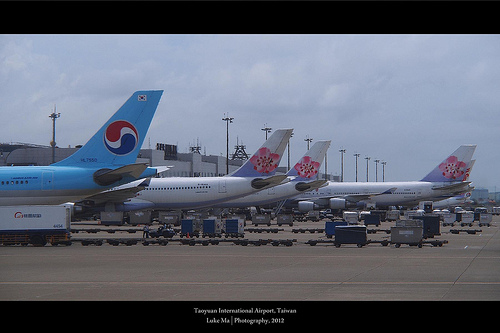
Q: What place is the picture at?
A: It is at the airport.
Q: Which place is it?
A: It is an airport.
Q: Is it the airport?
A: Yes, it is the airport.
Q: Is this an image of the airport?
A: Yes, it is showing the airport.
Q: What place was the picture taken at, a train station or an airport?
A: It was taken at an airport.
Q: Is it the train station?
A: No, it is the airport.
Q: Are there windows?
A: Yes, there are windows.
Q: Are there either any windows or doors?
A: Yes, there are windows.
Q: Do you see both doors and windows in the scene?
A: Yes, there are both windows and doors.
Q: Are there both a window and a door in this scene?
A: Yes, there are both a window and a door.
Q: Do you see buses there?
A: No, there are no buses.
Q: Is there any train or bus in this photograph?
A: No, there are no buses or trains.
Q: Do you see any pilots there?
A: No, there are no pilots.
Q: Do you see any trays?
A: No, there are no trays.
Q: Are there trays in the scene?
A: No, there are no trays.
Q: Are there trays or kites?
A: No, there are no trays or kites.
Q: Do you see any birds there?
A: No, there are no birds.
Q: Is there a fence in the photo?
A: No, there are no fences.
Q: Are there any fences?
A: No, there are no fences.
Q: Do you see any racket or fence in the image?
A: No, there are no fences or rackets.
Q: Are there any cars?
A: No, there are no cars.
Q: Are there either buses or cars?
A: No, there are no cars or buses.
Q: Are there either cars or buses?
A: No, there are no cars or buses.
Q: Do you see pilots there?
A: No, there are no pilots.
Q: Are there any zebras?
A: No, there are no zebras.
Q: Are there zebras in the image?
A: No, there are no zebras.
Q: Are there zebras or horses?
A: No, there are no zebras or horses.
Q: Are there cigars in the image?
A: No, there are no cigars.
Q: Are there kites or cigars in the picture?
A: No, there are no cigars or kites.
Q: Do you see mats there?
A: No, there are no mats.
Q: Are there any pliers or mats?
A: No, there are no mats or pliers.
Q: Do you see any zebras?
A: No, there are no zebras.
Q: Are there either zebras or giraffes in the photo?
A: No, there are no zebras or giraffes.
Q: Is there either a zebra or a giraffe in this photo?
A: No, there are no zebras or giraffes.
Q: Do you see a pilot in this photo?
A: No, there are no pilots.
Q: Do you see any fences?
A: No, there are no fences.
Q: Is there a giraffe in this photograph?
A: No, there are no giraffes.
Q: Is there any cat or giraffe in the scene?
A: No, there are no giraffes or cats.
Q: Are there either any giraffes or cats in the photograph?
A: No, there are no giraffes or cats.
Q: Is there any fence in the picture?
A: No, there are no fences.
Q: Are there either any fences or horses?
A: No, there are no fences or horses.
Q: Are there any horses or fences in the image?
A: No, there are no fences or horses.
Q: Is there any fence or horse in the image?
A: No, there are no fences or horses.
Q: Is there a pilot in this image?
A: No, there are no pilots.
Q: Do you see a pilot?
A: No, there are no pilots.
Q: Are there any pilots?
A: No, there are no pilots.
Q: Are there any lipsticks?
A: No, there are no lipsticks.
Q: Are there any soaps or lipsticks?
A: No, there are no lipsticks or soaps.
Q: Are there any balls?
A: No, there are no balls.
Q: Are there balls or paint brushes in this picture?
A: No, there are no balls or paint brushes.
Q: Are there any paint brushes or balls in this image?
A: No, there are no balls or paint brushes.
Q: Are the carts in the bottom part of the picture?
A: Yes, the carts are in the bottom of the image.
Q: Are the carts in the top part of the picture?
A: No, the carts are in the bottom of the image.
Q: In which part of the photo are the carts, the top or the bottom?
A: The carts are in the bottom of the image.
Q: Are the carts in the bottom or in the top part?
A: The carts are in the bottom of the image.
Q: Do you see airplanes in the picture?
A: Yes, there is an airplane.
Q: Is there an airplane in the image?
A: Yes, there is an airplane.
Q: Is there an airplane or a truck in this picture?
A: Yes, there is an airplane.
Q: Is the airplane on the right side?
A: Yes, the airplane is on the right of the image.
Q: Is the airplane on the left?
A: No, the airplane is on the right of the image.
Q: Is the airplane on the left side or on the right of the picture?
A: The airplane is on the right of the image.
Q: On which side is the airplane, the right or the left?
A: The airplane is on the right of the image.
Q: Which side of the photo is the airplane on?
A: The airplane is on the right of the image.